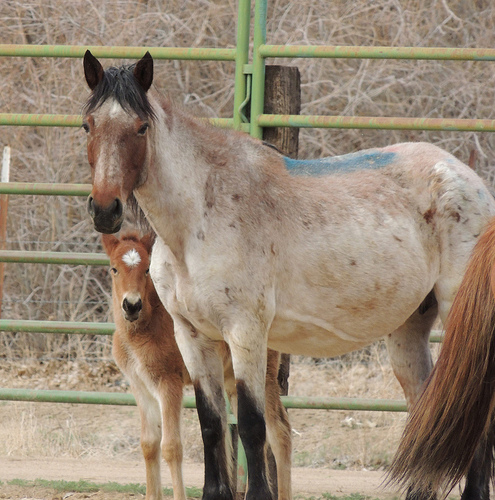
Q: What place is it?
A: It is a pen.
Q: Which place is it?
A: It is a pen.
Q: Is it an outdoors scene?
A: Yes, it is outdoors.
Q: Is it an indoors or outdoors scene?
A: It is outdoors.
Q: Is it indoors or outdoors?
A: It is outdoors.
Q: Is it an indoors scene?
A: No, it is outdoors.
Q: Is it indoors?
A: No, it is outdoors.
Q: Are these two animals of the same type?
A: Yes, all the animals are horses.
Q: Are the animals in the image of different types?
A: No, all the animals are horses.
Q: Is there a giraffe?
A: No, there are no giraffes.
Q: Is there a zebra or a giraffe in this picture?
A: No, there are no giraffes or zebras.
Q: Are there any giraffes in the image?
A: No, there are no giraffes.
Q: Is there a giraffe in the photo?
A: No, there are no giraffes.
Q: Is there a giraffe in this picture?
A: No, there are no giraffes.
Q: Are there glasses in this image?
A: No, there are no glasses.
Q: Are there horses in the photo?
A: Yes, there is a horse.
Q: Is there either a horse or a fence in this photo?
A: Yes, there is a horse.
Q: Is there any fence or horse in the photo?
A: Yes, there is a horse.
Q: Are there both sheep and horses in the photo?
A: No, there is a horse but no sheep.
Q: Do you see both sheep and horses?
A: No, there is a horse but no sheep.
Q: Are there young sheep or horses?
A: Yes, there is a young horse.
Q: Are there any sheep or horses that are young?
A: Yes, the horse is young.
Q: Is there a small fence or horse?
A: Yes, there is a small horse.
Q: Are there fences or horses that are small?
A: Yes, the horse is small.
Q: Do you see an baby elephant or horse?
A: Yes, there is a baby horse.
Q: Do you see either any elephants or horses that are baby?
A: Yes, the horse is a baby.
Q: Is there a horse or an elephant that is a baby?
A: Yes, the horse is a baby.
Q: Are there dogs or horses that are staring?
A: Yes, the horse is staring.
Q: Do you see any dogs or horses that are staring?
A: Yes, the horse is staring.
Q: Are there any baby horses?
A: Yes, there is a baby horse.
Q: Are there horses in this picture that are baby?
A: Yes, there is a horse that is a baby.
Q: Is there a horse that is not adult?
A: Yes, there is an baby horse.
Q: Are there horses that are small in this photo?
A: Yes, there is a small horse.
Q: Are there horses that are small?
A: Yes, there is a horse that is small.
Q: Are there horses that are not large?
A: Yes, there is a small horse.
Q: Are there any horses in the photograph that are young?
A: Yes, there is a young horse.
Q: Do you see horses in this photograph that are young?
A: Yes, there is a horse that is young.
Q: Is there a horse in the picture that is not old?
A: Yes, there is an young horse.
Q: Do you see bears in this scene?
A: No, there are no bears.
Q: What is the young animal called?
A: The animal is a horse.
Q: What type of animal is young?
A: The animal is a horse.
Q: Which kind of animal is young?
A: The animal is a horse.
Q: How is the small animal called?
A: The animal is a horse.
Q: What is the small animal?
A: The animal is a horse.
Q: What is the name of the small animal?
A: The animal is a horse.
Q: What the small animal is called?
A: The animal is a horse.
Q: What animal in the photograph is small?
A: The animal is a horse.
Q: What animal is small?
A: The animal is a horse.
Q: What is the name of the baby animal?
A: The animal is a horse.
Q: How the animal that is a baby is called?
A: The animal is a horse.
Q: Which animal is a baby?
A: The animal is a horse.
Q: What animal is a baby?
A: The animal is a horse.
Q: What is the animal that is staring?
A: The animal is a horse.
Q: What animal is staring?
A: The animal is a horse.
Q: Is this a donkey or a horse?
A: This is a horse.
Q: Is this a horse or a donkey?
A: This is a horse.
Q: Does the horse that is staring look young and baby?
A: Yes, the horse is young and baby.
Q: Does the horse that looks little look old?
A: No, the horse is young.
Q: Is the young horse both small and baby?
A: Yes, the horse is small and baby.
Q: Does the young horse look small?
A: Yes, the horse is small.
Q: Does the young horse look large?
A: No, the horse is small.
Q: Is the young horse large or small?
A: The horse is small.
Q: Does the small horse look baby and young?
A: Yes, the horse is a baby and young.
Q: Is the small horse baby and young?
A: Yes, the horse is a baby and young.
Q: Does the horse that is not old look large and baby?
A: No, the horse is a baby but small.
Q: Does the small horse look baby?
A: Yes, the horse is a baby.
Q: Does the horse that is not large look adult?
A: No, the horse is a baby.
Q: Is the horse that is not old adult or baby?
A: The horse is a baby.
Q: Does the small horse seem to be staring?
A: Yes, the horse is staring.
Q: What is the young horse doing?
A: The horse is staring.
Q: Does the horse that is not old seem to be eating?
A: No, the horse is staring.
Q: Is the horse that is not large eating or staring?
A: The horse is staring.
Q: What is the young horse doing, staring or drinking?
A: The horse is staring.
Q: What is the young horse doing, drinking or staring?
A: The horse is staring.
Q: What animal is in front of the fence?
A: The horse is in front of the fence.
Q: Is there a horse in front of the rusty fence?
A: Yes, there is a horse in front of the fence.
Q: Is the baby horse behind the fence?
A: No, the horse is in front of the fence.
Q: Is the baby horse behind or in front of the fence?
A: The horse is in front of the fence.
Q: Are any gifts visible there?
A: No, there are no gifts.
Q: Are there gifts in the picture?
A: No, there are no gifts.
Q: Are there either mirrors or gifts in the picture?
A: No, there are no gifts or mirrors.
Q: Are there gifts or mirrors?
A: No, there are no gifts or mirrors.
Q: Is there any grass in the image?
A: Yes, there is grass.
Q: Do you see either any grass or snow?
A: Yes, there is grass.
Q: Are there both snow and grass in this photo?
A: No, there is grass but no snow.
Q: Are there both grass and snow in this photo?
A: No, there is grass but no snow.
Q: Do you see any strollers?
A: No, there are no strollers.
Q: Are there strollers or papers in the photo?
A: No, there are no strollers or papers.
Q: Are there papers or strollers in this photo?
A: No, there are no strollers or papers.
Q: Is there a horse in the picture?
A: Yes, there is a horse.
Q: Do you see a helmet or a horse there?
A: Yes, there is a horse.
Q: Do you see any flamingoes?
A: No, there are no flamingoes.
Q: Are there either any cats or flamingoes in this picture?
A: No, there are no flamingoes or cats.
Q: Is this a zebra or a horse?
A: This is a horse.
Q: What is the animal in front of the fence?
A: The animal is a horse.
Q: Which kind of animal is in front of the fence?
A: The animal is a horse.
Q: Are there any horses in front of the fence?
A: Yes, there is a horse in front of the fence.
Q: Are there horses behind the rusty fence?
A: No, the horse is in front of the fence.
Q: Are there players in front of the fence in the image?
A: No, there is a horse in front of the fence.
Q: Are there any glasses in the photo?
A: No, there are no glasses.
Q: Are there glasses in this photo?
A: No, there are no glasses.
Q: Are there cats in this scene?
A: No, there are no cats.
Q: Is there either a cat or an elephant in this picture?
A: No, there are no cats or elephants.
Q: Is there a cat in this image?
A: No, there are no cats.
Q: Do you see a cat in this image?
A: No, there are no cats.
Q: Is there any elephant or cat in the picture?
A: No, there are no cats or elephants.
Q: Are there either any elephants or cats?
A: No, there are no cats or elephants.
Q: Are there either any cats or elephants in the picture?
A: No, there are no cats or elephants.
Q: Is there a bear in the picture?
A: No, there are no bears.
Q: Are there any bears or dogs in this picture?
A: No, there are no bears or dogs.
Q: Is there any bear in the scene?
A: No, there are no bears.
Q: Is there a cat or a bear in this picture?
A: No, there are no bears or cats.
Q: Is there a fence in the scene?
A: Yes, there is a fence.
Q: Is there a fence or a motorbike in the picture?
A: Yes, there is a fence.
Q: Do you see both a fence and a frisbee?
A: No, there is a fence but no frisbees.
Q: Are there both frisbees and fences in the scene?
A: No, there is a fence but no frisbees.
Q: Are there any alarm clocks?
A: No, there are no alarm clocks.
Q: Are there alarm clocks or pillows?
A: No, there are no alarm clocks or pillows.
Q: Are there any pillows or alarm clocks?
A: No, there are no alarm clocks or pillows.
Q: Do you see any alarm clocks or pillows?
A: No, there are no alarm clocks or pillows.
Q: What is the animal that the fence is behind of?
A: The animal is a horse.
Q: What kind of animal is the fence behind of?
A: The fence is behind the horse.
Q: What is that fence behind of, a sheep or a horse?
A: The fence is behind a horse.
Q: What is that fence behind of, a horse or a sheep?
A: The fence is behind a horse.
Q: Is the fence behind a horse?
A: Yes, the fence is behind a horse.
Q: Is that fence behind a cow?
A: No, the fence is behind a horse.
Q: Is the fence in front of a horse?
A: No, the fence is behind a horse.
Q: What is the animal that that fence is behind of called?
A: The animal is a horse.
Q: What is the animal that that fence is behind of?
A: The animal is a horse.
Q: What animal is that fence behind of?
A: The fence is behind the horse.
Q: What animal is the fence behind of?
A: The fence is behind the horse.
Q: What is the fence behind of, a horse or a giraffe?
A: The fence is behind a horse.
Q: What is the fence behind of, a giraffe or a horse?
A: The fence is behind a horse.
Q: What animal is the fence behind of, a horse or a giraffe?
A: The fence is behind a horse.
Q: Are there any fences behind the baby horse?
A: Yes, there is a fence behind the horse.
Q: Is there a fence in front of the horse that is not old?
A: No, the fence is behind the horse.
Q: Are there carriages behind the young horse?
A: No, there is a fence behind the horse.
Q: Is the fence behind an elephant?
A: No, the fence is behind the horse.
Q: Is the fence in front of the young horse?
A: No, the fence is behind the horse.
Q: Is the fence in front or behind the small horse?
A: The fence is behind the horse.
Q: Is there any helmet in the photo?
A: No, there are no helmets.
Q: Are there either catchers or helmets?
A: No, there are no helmets or catchers.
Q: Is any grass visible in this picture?
A: Yes, there is grass.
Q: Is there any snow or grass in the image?
A: Yes, there is grass.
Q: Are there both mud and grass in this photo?
A: No, there is grass but no mud.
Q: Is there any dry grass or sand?
A: Yes, there is dry grass.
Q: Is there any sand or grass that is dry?
A: Yes, the grass is dry.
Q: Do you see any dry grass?
A: Yes, there is dry grass.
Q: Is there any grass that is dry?
A: Yes, there is grass that is dry.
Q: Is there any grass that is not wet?
A: Yes, there is dry grass.